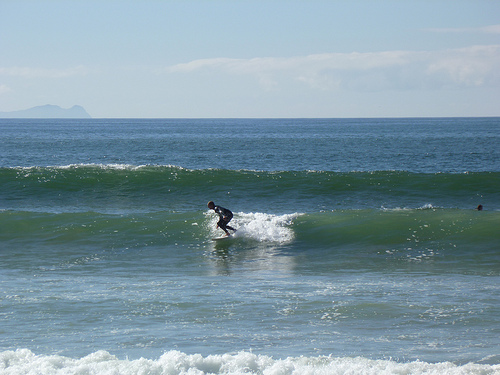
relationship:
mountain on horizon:
[9, 96, 99, 120] [8, 114, 440, 124]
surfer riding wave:
[205, 196, 240, 242] [189, 204, 338, 228]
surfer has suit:
[206, 200, 237, 238] [214, 208, 234, 229]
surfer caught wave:
[205, 196, 240, 242] [108, 193, 338, 237]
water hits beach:
[48, 311, 382, 342] [20, 343, 401, 373]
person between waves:
[473, 203, 484, 212] [435, 161, 496, 248]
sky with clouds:
[0, 0, 500, 120] [194, 50, 398, 74]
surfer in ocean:
[206, 200, 237, 238] [121, 128, 343, 278]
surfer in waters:
[206, 200, 237, 238] [92, 245, 273, 368]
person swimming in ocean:
[472, 199, 485, 213] [345, 141, 496, 253]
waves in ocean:
[29, 145, 131, 245] [84, 137, 379, 213]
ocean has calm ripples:
[36, 125, 407, 304] [159, 129, 298, 158]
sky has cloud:
[2, 5, 484, 120] [159, 40, 498, 98]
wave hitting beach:
[11, 331, 421, 372] [12, 270, 484, 361]